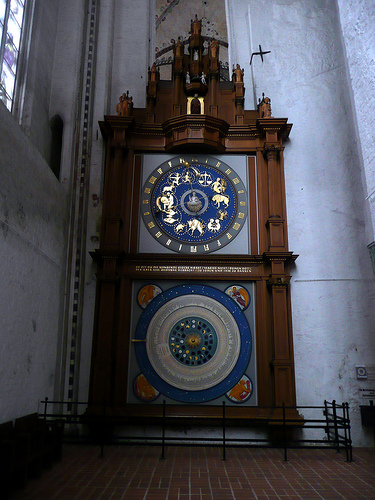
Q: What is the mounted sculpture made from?
A: Wood.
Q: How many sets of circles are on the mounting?
A: 2.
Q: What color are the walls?
A: White.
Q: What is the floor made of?
A: Brick.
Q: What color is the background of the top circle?
A: Blue.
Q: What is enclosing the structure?
A: Metal fencing.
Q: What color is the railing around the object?
A: Black.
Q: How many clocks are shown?
A: One.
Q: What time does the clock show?
A: 11:44.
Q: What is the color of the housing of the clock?
A: Brown.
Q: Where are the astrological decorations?
A: Clock face.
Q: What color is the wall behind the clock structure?
A: Gray.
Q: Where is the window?
A: Upper left side of the image.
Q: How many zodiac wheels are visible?
A: Just one.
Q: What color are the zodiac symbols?
A: Gold.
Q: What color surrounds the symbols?
A: Blue.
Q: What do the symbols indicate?
A: The signs of the Western zodiac.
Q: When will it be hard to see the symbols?
A: At night.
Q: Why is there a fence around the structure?
A: To keep people from touching it.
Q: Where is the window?
A: To the left of the structure.